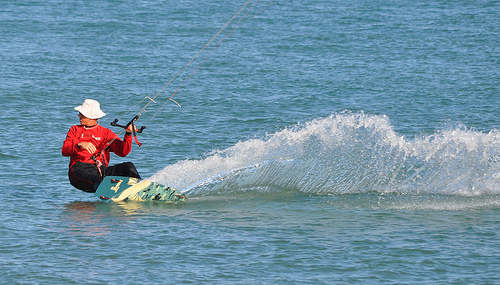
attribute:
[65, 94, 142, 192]
man — kite boarding, windsurfing, leaning, parasailing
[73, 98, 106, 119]
hat — white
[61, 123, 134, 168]
shirt — red, long-sleeved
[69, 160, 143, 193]
pants — black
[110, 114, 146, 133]
handles — black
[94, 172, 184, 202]
surfboard — blue, white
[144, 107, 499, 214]
wave — splashing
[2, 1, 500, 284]
water — blue, calm, spraying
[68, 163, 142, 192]
trousers — black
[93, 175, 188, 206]
board — sideways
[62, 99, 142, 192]
person — surfing, windsurfing